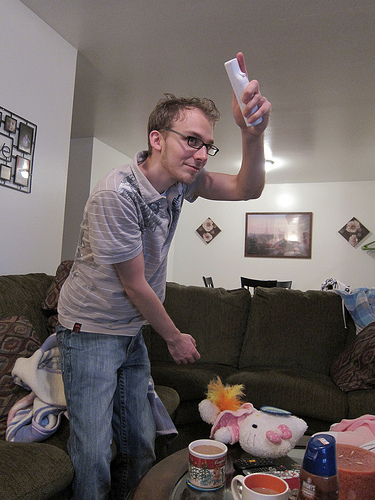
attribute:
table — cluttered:
[167, 377, 374, 491]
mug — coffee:
[184, 434, 230, 491]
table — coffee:
[133, 432, 370, 494]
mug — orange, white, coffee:
[229, 469, 289, 496]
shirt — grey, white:
[56, 149, 211, 337]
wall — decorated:
[170, 182, 372, 295]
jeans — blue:
[58, 321, 162, 498]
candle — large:
[327, 442, 369, 496]